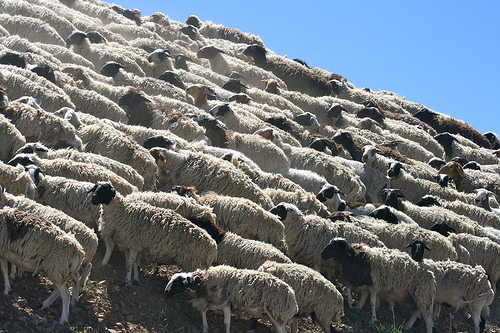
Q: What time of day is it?
A: Day time.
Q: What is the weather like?
A: Sunny.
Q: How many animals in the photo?
A: Dozens.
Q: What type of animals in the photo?
A: Sheep.